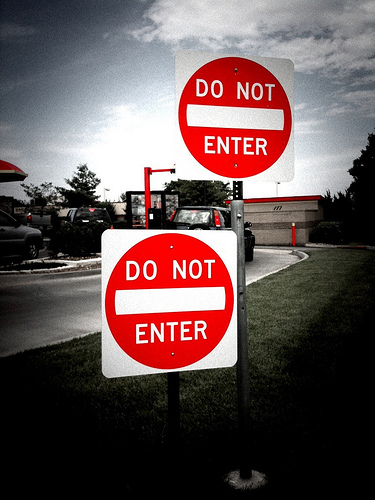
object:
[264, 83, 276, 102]
letter t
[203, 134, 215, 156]
letter e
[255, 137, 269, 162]
letter r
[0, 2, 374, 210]
sky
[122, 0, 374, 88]
cloud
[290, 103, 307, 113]
cloud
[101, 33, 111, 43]
cloud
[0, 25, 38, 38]
cloud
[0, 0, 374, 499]
background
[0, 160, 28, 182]
roof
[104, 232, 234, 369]
circle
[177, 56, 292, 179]
circle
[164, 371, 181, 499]
sign post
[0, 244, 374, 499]
grass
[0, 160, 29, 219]
restaurant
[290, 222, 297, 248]
pole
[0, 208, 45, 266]
drive through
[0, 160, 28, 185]
umbrella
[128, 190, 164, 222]
menu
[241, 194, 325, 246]
building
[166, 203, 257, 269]
drivethru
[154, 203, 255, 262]
car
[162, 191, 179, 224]
order board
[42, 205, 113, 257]
car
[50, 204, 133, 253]
drivethru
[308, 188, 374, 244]
shrubs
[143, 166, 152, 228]
pole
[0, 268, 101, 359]
pavement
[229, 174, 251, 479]
pole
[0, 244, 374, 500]
ground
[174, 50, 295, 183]
sign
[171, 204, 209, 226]
windows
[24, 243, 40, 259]
wheel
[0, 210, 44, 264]
car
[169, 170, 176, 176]
light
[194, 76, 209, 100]
letter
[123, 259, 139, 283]
letter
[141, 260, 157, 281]
letter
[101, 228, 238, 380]
sign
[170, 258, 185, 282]
letter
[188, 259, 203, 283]
letter